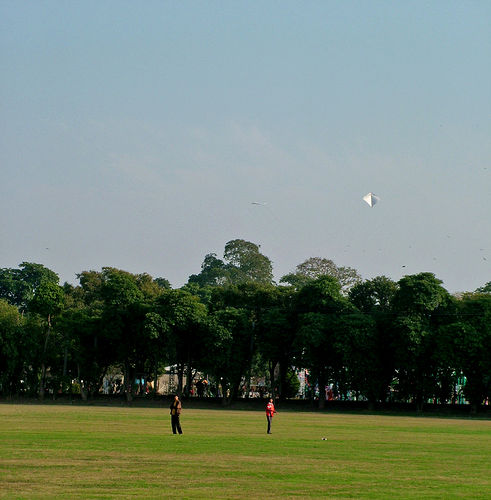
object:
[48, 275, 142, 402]
tree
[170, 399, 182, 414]
jacket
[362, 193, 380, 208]
kite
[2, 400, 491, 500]
grass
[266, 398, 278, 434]
body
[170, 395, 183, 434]
body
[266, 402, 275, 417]
jacket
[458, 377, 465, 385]
shutters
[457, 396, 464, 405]
shutters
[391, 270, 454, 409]
tree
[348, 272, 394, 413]
tree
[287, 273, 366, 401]
tree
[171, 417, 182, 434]
blue jeans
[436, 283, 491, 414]
tree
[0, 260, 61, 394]
tree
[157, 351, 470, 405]
buildings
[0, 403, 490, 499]
field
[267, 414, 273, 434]
jeans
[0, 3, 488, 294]
sky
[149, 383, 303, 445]
sun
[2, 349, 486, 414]
side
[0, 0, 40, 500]
left